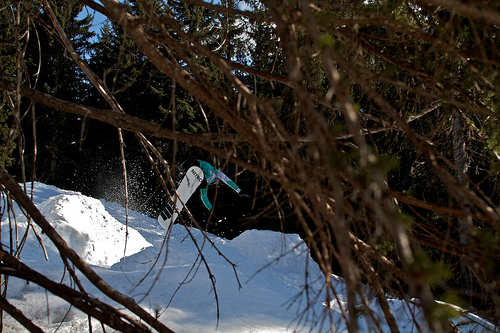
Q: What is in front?
A: Branches.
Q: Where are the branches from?
A: A tree.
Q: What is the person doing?
A: Snowboarding.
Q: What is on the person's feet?
A: A snowboard.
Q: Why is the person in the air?
A: A jump.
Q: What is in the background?
A: Trees.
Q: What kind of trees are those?
A: Evergreens.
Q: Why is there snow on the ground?
A: It's winter.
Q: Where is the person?
A: In the air.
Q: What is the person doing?
A: Snowboarding.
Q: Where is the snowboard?
A: Under the person.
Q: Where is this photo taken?
A: In the forest.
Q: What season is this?
A: It is winter.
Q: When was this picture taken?
A: Day time.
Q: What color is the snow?
A: White.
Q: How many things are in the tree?
A: One.